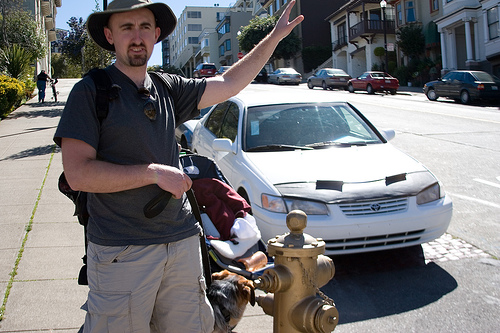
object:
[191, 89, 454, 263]
car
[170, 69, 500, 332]
street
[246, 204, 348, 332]
hydrant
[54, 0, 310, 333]
man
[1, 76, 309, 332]
sidewalk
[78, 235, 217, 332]
pants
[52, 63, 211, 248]
t-shirt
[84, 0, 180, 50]
hat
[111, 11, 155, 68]
face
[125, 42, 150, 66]
goatee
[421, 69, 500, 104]
car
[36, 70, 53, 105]
man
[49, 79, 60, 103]
bike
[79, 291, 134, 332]
pocket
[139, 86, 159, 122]
sunglasses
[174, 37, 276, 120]
arm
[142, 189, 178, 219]
leash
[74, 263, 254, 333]
dog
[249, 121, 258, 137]
sticker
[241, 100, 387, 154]
window